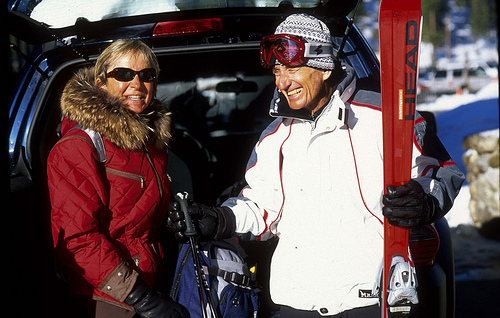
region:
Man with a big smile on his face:
[259, 57, 332, 105]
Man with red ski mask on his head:
[261, 14, 331, 114]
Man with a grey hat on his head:
[263, 18, 339, 121]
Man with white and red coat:
[246, 78, 458, 311]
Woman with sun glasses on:
[60, 33, 172, 139]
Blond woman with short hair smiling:
[98, 41, 167, 120]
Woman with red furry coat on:
[42, 100, 175, 315]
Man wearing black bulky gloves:
[370, 175, 470, 240]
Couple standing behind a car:
[29, 11, 458, 311]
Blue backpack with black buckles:
[144, 208, 273, 315]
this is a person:
[45, 21, 178, 306]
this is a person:
[188, 7, 437, 314]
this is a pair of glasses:
[110, 65, 160, 78]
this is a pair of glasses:
[257, 31, 314, 62]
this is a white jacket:
[237, 100, 385, 312]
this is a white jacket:
[42, 80, 178, 298]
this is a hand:
[376, 182, 441, 226]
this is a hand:
[161, 192, 236, 242]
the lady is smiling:
[93, 28, 167, 130]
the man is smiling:
[256, 6, 368, 107]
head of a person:
[233, 8, 350, 133]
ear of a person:
[316, 62, 343, 86]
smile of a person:
[120, 85, 160, 113]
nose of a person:
[275, 72, 292, 97]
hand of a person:
[369, 171, 433, 236]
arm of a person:
[219, 189, 311, 239]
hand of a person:
[169, 188, 226, 243]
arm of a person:
[62, 178, 126, 303]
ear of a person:
[72, 59, 116, 104]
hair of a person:
[85, 25, 152, 75]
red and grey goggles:
[261, 36, 329, 65]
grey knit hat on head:
[273, 14, 333, 71]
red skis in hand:
[378, 1, 419, 317]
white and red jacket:
[224, 65, 461, 307]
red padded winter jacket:
[49, 67, 180, 309]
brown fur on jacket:
[58, 68, 175, 145]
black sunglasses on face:
[103, 68, 155, 83]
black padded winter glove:
[382, 181, 437, 229]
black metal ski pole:
[178, 195, 213, 317]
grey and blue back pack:
[178, 240, 257, 317]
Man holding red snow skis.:
[221, 1, 465, 317]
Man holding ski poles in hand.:
[164, 177, 251, 317]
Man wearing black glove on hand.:
[381, 174, 438, 228]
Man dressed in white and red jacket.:
[188, 67, 474, 317]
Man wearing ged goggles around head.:
[256, 29, 337, 66]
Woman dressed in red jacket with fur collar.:
[38, 62, 210, 309]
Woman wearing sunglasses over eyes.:
[96, 62, 164, 86]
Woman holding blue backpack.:
[165, 239, 260, 316]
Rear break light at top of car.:
[143, 11, 231, 46]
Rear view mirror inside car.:
[211, 72, 266, 102]